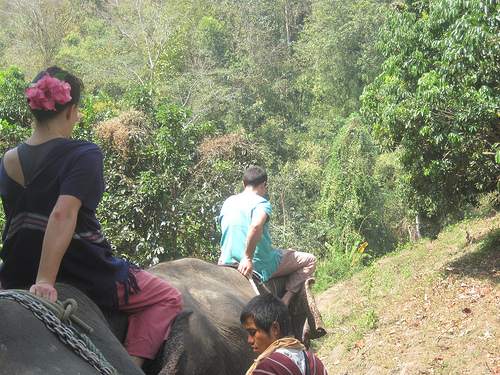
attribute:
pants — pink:
[114, 261, 183, 356]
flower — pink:
[25, 71, 71, 110]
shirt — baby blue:
[205, 181, 297, 279]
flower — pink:
[18, 68, 75, 122]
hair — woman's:
[23, 62, 83, 126]